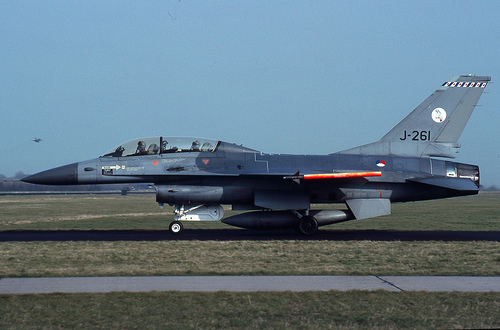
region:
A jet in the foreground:
[3, 55, 498, 240]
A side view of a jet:
[1, 57, 498, 247]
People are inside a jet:
[108, 131, 215, 161]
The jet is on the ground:
[3, 66, 498, 258]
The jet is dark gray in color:
[1, 60, 493, 245]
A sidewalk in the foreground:
[6, 260, 498, 312]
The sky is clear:
[1, 3, 498, 185]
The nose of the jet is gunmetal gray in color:
[16, 155, 87, 198]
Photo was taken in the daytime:
[1, 3, 492, 328]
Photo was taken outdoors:
[1, 5, 498, 328]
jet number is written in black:
[399, 130, 432, 141]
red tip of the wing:
[304, 169, 387, 178]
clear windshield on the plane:
[110, 136, 215, 157]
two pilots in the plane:
[136, 135, 201, 152]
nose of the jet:
[17, 161, 80, 186]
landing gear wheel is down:
[166, 205, 193, 236]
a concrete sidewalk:
[1, 274, 498, 294]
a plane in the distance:
[33, 135, 45, 144]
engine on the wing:
[151, 185, 254, 203]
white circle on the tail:
[431, 107, 448, 122]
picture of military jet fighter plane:
[32, 62, 487, 252]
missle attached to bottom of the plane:
[205, 198, 371, 248]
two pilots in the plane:
[119, 128, 224, 150]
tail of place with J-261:
[393, 61, 490, 163]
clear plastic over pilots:
[101, 126, 222, 169]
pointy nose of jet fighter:
[10, 143, 102, 203]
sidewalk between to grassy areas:
[40, 270, 497, 320]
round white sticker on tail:
[426, 100, 453, 126]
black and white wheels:
[162, 208, 194, 238]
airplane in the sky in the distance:
[22, 114, 60, 161]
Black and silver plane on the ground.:
[119, 148, 180, 149]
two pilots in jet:
[120, 133, 219, 158]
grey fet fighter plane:
[1, 55, 487, 264]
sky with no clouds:
[102, 46, 339, 112]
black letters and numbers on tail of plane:
[390, 123, 440, 150]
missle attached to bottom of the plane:
[225, 203, 358, 232]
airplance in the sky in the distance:
[15, 128, 52, 151]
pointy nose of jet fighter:
[14, 147, 115, 194]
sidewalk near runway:
[26, 254, 478, 300]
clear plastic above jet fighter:
[114, 132, 224, 166]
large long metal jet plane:
[15, 76, 489, 238]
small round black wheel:
[169, 219, 185, 235]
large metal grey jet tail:
[329, 76, 491, 163]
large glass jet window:
[101, 134, 217, 157]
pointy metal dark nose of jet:
[19, 160, 83, 185]